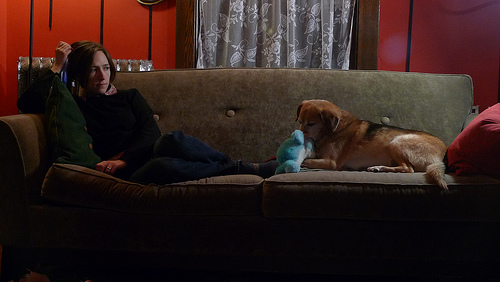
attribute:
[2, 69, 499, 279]
couch — green, brown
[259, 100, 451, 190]
dog — tan, black, brown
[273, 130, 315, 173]
toy — blue, white, green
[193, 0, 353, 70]
curtains — white, gray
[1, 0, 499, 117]
walls — red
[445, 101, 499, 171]
red pillow — large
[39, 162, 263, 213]
cushion — green